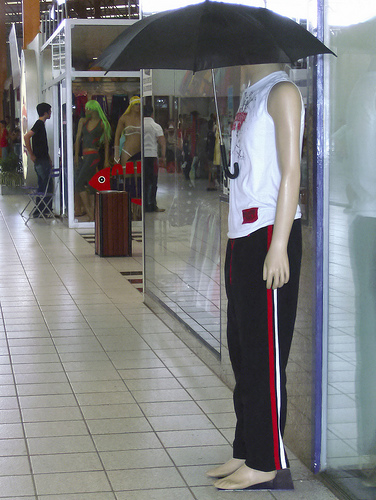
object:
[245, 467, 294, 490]
display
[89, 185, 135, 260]
trash can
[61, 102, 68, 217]
window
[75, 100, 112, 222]
mannequin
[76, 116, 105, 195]
clothing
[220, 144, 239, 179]
handle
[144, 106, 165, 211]
reflection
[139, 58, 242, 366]
window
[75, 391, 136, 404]
floor tile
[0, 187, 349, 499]
floor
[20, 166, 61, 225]
chair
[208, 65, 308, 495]
mannequin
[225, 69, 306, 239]
tank top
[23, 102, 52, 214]
man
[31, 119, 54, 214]
clothes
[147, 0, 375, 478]
store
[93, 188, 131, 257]
fountain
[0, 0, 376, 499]
mall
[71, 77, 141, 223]
window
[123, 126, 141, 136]
bra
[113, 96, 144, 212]
mannequin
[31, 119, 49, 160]
shirt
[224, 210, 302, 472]
pants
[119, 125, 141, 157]
bikini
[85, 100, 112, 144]
hair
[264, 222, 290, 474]
stripes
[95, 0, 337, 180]
umbrella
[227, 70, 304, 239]
shirt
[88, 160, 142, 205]
graphics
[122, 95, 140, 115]
hair